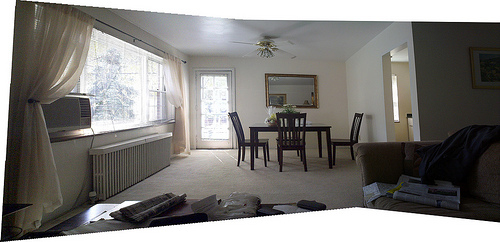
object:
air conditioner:
[41, 92, 91, 133]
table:
[249, 125, 333, 170]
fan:
[230, 36, 295, 62]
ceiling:
[108, 8, 394, 62]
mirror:
[265, 73, 319, 108]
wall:
[188, 55, 351, 149]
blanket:
[416, 125, 500, 185]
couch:
[353, 141, 500, 222]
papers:
[362, 174, 461, 211]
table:
[43, 201, 316, 237]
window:
[34, 3, 175, 143]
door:
[196, 71, 233, 149]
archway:
[379, 21, 415, 59]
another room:
[391, 48, 415, 142]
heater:
[88, 132, 172, 205]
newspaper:
[110, 188, 187, 223]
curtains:
[2, 0, 95, 231]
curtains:
[164, 52, 187, 156]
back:
[464, 143, 500, 205]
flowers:
[282, 105, 296, 126]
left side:
[0, 0, 274, 241]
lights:
[258, 49, 276, 58]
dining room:
[145, 21, 420, 174]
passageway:
[382, 42, 414, 142]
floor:
[34, 149, 363, 232]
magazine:
[62, 215, 185, 236]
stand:
[327, 130, 333, 168]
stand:
[317, 131, 322, 157]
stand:
[251, 132, 255, 169]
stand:
[255, 132, 259, 158]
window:
[392, 75, 400, 122]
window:
[201, 76, 230, 138]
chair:
[331, 113, 363, 165]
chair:
[274, 110, 313, 174]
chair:
[228, 112, 271, 170]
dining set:
[228, 111, 364, 172]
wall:
[345, 21, 421, 153]